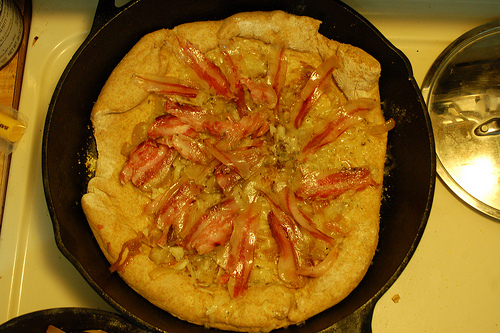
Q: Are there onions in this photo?
A: Yes, there are onions.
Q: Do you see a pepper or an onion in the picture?
A: Yes, there are onions.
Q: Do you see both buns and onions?
A: No, there are onions but no buns.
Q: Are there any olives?
A: No, there are no olives.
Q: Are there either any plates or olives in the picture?
A: No, there are no olives or plates.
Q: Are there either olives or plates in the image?
A: No, there are no olives or plates.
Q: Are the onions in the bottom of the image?
A: Yes, the onions are in the bottom of the image.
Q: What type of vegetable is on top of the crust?
A: The vegetables are onions.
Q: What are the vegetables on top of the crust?
A: The vegetables are onions.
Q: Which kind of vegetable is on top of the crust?
A: The vegetables are onions.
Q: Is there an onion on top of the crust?
A: Yes, there are onions on top of the crust.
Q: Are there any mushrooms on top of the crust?
A: No, there are onions on top of the crust.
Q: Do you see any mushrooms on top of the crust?
A: No, there are onions on top of the crust.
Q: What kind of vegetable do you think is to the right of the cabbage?
A: The vegetables are onions.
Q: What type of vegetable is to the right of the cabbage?
A: The vegetables are onions.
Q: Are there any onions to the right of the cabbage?
A: Yes, there are onions to the right of the cabbage.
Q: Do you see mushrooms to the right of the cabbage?
A: No, there are onions to the right of the cabbage.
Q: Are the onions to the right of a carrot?
A: No, the onions are to the right of the cabbage.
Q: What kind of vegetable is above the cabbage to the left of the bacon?
A: The vegetables are onions.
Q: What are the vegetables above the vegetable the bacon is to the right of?
A: The vegetables are onions.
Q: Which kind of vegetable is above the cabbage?
A: The vegetables are onions.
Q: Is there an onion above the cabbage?
A: Yes, there are onions above the cabbage.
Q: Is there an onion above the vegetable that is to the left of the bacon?
A: Yes, there are onions above the cabbage.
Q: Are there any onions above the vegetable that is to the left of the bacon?
A: Yes, there are onions above the cabbage.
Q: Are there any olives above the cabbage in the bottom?
A: No, there are onions above the cabbage.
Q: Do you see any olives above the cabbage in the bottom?
A: No, there are onions above the cabbage.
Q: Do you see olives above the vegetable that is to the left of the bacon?
A: No, there are onions above the cabbage.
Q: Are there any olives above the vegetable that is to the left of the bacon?
A: No, there are onions above the cabbage.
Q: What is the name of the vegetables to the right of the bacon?
A: The vegetables are onions.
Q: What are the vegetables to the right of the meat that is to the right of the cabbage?
A: The vegetables are onions.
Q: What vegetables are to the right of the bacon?
A: The vegetables are onions.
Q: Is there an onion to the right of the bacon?
A: Yes, there are onions to the right of the bacon.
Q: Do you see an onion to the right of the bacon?
A: Yes, there are onions to the right of the bacon.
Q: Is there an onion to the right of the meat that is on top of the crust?
A: Yes, there are onions to the right of the bacon.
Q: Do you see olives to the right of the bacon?
A: No, there are onions to the right of the bacon.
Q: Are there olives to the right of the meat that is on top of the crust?
A: No, there are onions to the right of the bacon.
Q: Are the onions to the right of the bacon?
A: Yes, the onions are to the right of the bacon.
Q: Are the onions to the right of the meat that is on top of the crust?
A: Yes, the onions are to the right of the bacon.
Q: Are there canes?
A: No, there are no canes.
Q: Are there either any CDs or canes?
A: No, there are no canes or cds.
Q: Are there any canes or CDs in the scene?
A: No, there are no canes or cds.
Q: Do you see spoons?
A: No, there are no spoons.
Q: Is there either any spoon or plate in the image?
A: No, there are no spoons or plates.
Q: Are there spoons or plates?
A: No, there are no spoons or plates.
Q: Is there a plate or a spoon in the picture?
A: No, there are no spoons or plates.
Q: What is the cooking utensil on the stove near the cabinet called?
A: The cooking utensil is a skillet.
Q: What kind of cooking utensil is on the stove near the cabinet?
A: The cooking utensil is a skillet.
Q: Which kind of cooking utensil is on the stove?
A: The cooking utensil is a skillet.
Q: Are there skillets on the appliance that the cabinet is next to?
A: Yes, there is a skillet on the stove.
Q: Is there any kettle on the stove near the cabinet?
A: No, there is a skillet on the stove.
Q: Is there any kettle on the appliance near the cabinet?
A: No, there is a skillet on the stove.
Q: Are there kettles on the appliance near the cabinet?
A: No, there is a skillet on the stove.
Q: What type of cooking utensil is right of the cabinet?
A: The cooking utensil is a skillet.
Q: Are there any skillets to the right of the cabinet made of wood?
A: Yes, there is a skillet to the right of the cabinet.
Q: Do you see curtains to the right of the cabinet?
A: No, there is a skillet to the right of the cabinet.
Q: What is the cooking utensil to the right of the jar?
A: The cooking utensil is a skillet.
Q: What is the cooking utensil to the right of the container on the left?
A: The cooking utensil is a skillet.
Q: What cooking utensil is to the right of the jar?
A: The cooking utensil is a skillet.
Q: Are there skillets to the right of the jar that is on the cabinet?
A: Yes, there is a skillet to the right of the jar.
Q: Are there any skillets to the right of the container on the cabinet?
A: Yes, there is a skillet to the right of the jar.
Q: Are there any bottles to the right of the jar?
A: No, there is a skillet to the right of the jar.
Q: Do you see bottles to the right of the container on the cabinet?
A: No, there is a skillet to the right of the jar.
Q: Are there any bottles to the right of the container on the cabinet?
A: No, there is a skillet to the right of the jar.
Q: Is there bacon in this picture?
A: Yes, there is bacon.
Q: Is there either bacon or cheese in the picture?
A: Yes, there is bacon.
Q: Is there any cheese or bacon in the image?
A: Yes, there is bacon.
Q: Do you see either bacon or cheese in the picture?
A: Yes, there is bacon.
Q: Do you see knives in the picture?
A: No, there are no knives.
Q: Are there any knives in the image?
A: No, there are no knives.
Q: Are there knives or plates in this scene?
A: No, there are no knives or plates.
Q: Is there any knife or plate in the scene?
A: No, there are no knives or plates.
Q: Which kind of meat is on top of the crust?
A: The meat is bacon.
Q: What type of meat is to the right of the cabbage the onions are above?
A: The meat is bacon.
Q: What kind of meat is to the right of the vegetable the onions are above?
A: The meat is bacon.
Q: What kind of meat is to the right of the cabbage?
A: The meat is bacon.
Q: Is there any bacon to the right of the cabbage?
A: Yes, there is bacon to the right of the cabbage.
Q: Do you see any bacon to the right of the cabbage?
A: Yes, there is bacon to the right of the cabbage.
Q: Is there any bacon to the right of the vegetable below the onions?
A: Yes, there is bacon to the right of the cabbage.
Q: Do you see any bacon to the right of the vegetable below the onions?
A: Yes, there is bacon to the right of the cabbage.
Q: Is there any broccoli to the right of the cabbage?
A: No, there is bacon to the right of the cabbage.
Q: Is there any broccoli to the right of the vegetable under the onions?
A: No, there is bacon to the right of the cabbage.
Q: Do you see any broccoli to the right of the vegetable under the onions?
A: No, there is bacon to the right of the cabbage.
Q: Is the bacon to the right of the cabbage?
A: Yes, the bacon is to the right of the cabbage.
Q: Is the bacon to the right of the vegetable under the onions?
A: Yes, the bacon is to the right of the cabbage.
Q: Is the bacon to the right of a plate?
A: No, the bacon is to the right of the cabbage.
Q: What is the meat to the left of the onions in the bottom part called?
A: The meat is bacon.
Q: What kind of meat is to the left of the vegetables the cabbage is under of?
A: The meat is bacon.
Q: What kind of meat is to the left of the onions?
A: The meat is bacon.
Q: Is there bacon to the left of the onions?
A: Yes, there is bacon to the left of the onions.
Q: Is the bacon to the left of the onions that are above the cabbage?
A: Yes, the bacon is to the left of the onions.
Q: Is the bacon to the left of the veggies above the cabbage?
A: Yes, the bacon is to the left of the onions.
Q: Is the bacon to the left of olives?
A: No, the bacon is to the left of the onions.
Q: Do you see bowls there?
A: No, there are no bowls.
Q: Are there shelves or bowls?
A: No, there are no bowls or shelves.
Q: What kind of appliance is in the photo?
A: The appliance is a stove.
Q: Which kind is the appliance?
A: The appliance is a stove.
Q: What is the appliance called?
A: The appliance is a stove.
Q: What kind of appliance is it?
A: The appliance is a stove.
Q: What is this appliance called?
A: This is a stove.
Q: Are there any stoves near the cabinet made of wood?
A: Yes, there is a stove near the cabinet.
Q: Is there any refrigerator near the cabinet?
A: No, there is a stove near the cabinet.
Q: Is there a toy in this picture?
A: No, there are no toys.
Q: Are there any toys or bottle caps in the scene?
A: No, there are no toys or bottle caps.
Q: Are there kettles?
A: No, there are no kettles.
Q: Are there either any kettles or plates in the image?
A: No, there are no kettles or plates.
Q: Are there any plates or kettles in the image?
A: No, there are no kettles or plates.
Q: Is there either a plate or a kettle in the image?
A: No, there are no kettles or plates.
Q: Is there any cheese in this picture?
A: Yes, there is cheese.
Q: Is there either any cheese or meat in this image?
A: Yes, there is cheese.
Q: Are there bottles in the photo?
A: No, there are no bottles.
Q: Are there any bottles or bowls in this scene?
A: No, there are no bottles or bowls.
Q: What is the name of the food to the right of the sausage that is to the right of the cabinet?
A: The food is cheese.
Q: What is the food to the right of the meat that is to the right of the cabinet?
A: The food is cheese.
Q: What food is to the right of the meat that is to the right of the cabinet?
A: The food is cheese.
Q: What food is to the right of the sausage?
A: The food is cheese.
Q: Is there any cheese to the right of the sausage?
A: Yes, there is cheese to the right of the sausage.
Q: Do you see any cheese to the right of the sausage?
A: Yes, there is cheese to the right of the sausage.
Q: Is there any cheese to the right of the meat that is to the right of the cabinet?
A: Yes, there is cheese to the right of the sausage.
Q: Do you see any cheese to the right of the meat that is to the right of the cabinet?
A: Yes, there is cheese to the right of the sausage.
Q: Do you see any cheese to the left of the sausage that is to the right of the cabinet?
A: No, the cheese is to the right of the sausage.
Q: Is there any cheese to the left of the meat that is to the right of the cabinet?
A: No, the cheese is to the right of the sausage.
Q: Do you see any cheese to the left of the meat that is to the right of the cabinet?
A: No, the cheese is to the right of the sausage.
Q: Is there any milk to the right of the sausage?
A: No, there is cheese to the right of the sausage.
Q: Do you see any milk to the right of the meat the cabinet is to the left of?
A: No, there is cheese to the right of the sausage.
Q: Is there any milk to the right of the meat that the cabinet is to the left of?
A: No, there is cheese to the right of the sausage.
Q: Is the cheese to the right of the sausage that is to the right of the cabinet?
A: Yes, the cheese is to the right of the sausage.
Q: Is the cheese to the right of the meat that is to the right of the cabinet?
A: Yes, the cheese is to the right of the sausage.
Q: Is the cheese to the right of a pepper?
A: No, the cheese is to the right of the sausage.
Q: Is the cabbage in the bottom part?
A: Yes, the cabbage is in the bottom of the image.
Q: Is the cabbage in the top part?
A: No, the cabbage is in the bottom of the image.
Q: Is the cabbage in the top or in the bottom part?
A: The cabbage is in the bottom of the image.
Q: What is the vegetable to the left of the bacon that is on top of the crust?
A: The vegetable is a cabbage.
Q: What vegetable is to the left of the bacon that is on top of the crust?
A: The vegetable is a cabbage.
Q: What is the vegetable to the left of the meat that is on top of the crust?
A: The vegetable is a cabbage.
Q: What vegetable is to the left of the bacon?
A: The vegetable is a cabbage.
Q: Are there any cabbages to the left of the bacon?
A: Yes, there is a cabbage to the left of the bacon.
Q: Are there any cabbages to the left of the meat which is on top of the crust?
A: Yes, there is a cabbage to the left of the bacon.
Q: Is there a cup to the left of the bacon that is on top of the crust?
A: No, there is a cabbage to the left of the bacon.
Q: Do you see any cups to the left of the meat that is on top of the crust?
A: No, there is a cabbage to the left of the bacon.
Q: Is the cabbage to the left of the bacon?
A: Yes, the cabbage is to the left of the bacon.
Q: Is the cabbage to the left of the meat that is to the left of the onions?
A: Yes, the cabbage is to the left of the bacon.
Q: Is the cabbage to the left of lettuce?
A: No, the cabbage is to the left of the bacon.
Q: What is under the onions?
A: The cabbage is under the onions.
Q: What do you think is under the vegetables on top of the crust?
A: The cabbage is under the onions.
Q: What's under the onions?
A: The cabbage is under the onions.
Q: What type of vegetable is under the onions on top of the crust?
A: The vegetable is a cabbage.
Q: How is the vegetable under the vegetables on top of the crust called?
A: The vegetable is a cabbage.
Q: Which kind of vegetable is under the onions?
A: The vegetable is a cabbage.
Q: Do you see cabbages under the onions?
A: Yes, there is a cabbage under the onions.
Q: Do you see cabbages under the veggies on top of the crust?
A: Yes, there is a cabbage under the onions.